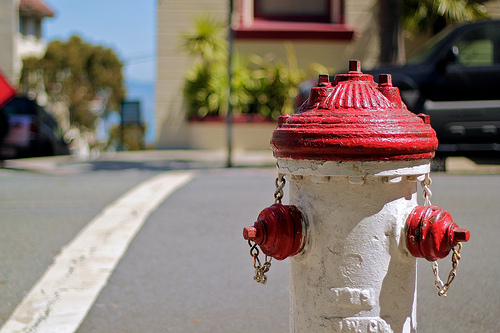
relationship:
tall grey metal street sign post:
[212, 131, 243, 187] [215, 51, 239, 182]